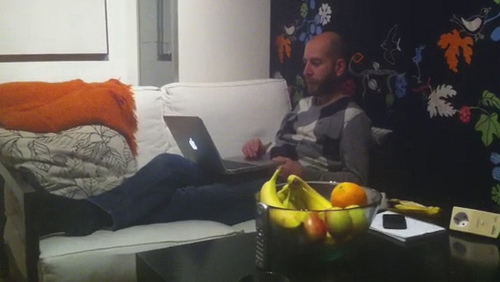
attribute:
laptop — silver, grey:
[161, 112, 285, 177]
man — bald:
[23, 34, 389, 237]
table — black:
[132, 187, 500, 280]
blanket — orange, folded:
[0, 73, 144, 140]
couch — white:
[2, 74, 306, 279]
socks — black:
[22, 167, 104, 238]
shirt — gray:
[251, 93, 373, 193]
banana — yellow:
[258, 168, 328, 226]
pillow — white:
[161, 75, 294, 172]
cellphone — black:
[382, 212, 408, 231]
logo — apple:
[186, 135, 201, 154]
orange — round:
[323, 178, 368, 206]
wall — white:
[2, 1, 139, 88]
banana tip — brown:
[277, 163, 292, 179]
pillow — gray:
[0, 130, 131, 193]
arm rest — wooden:
[0, 157, 46, 281]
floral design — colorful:
[271, 1, 499, 206]